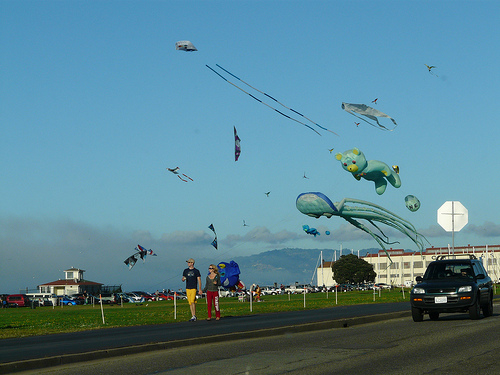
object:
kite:
[341, 99, 398, 131]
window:
[376, 262, 388, 269]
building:
[313, 251, 498, 289]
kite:
[294, 192, 432, 272]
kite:
[334, 147, 402, 195]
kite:
[224, 122, 245, 166]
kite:
[201, 218, 222, 255]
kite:
[133, 33, 328, 133]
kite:
[338, 96, 400, 137]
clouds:
[0, 213, 499, 293]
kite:
[301, 222, 319, 235]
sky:
[0, 0, 499, 288]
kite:
[123, 244, 159, 272]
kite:
[327, 137, 415, 189]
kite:
[231, 123, 242, 160]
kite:
[174, 40, 340, 137]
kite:
[330, 90, 459, 176]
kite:
[424, 63, 438, 76]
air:
[0, 0, 499, 375]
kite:
[168, 166, 194, 183]